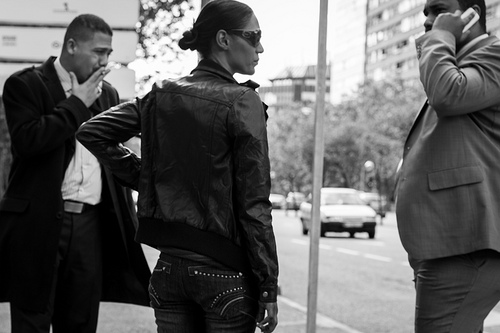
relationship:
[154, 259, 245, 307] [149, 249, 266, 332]
studs on pants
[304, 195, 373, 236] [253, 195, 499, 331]
car driving on road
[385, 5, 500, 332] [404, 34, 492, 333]
man wearing a business suit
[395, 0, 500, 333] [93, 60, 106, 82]
man holding hand to mouth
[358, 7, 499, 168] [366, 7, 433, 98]
building with windows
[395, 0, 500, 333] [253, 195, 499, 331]
man standing by road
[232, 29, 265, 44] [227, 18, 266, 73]
sunglasses on her face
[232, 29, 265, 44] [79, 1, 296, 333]
sunglasses worn by woman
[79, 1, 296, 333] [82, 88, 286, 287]
woman wearing jacket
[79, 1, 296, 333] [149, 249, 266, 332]
woman wearing pants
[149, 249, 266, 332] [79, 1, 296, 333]
pants of woman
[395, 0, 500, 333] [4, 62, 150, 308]
man wearing a coat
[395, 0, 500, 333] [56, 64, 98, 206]
man wearing a shirt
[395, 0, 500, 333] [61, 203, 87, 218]
man wearing belt clip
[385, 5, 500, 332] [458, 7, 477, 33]
man using a phone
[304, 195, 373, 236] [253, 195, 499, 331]
car on road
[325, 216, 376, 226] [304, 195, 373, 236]
headlights of car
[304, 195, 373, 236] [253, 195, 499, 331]
car in road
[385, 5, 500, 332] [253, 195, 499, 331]
man standing beside road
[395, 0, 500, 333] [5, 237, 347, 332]
man standing on sidewalk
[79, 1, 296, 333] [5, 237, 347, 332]
woman on sidewalk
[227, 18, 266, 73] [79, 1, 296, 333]
face of woman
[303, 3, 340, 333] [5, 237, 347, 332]
pole on sidewalk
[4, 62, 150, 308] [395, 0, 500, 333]
coat on man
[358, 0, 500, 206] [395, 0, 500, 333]
building behind man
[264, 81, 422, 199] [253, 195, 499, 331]
trees growing along road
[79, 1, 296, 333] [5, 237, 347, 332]
woman standing on sidewalk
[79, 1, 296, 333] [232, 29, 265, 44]
woman wearing sunglasses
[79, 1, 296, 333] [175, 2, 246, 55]
woman has hair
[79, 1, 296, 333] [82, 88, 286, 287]
woman wearing a jacket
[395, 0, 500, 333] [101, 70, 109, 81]
man smoking a cigarette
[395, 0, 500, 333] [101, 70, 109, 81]
man with a cigarette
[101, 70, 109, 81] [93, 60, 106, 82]
cigarette in h mouth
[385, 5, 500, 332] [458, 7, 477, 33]
man talking on a phone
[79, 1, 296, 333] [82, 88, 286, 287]
woman in a jacket